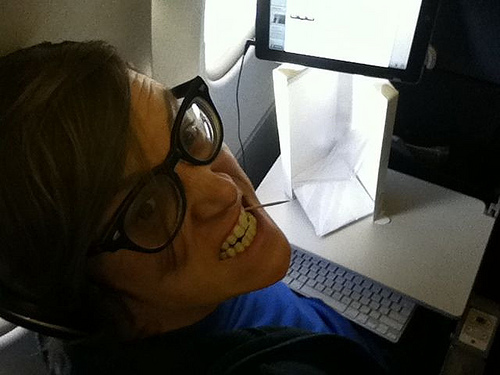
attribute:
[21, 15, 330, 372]
guy — wearing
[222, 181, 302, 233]
pick — tooth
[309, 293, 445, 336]
keyboard — gray, white, grey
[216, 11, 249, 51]
window — plane, open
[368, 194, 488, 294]
table — white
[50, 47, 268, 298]
glass — black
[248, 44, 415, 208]
book — propped up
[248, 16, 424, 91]
screen — tablet, on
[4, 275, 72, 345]
phone — head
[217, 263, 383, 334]
shirt — blue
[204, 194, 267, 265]
teeth — white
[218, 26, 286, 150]
cord — black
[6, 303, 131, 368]
chair — back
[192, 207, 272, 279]
tooth — white